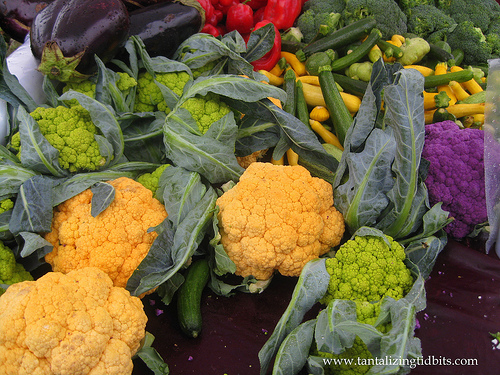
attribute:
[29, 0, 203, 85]
eggplant — dark purple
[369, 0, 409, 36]
broccoli — green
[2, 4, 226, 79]
eggplant — large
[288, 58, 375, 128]
squash — yellow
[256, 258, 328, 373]
leaf — dark green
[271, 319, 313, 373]
leaf — dark green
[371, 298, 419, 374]
leaf — dark green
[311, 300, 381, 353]
leaf — dark green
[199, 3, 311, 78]
pepper — red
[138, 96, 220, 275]
leaves — dark green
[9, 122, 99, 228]
leaves — green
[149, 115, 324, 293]
leaves — green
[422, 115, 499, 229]
cauliflower — purple